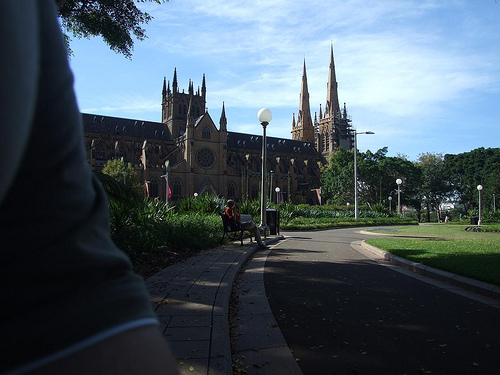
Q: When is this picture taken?
A: While touring.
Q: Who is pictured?
A: Man.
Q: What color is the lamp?
A: White.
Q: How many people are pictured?
A: Two.